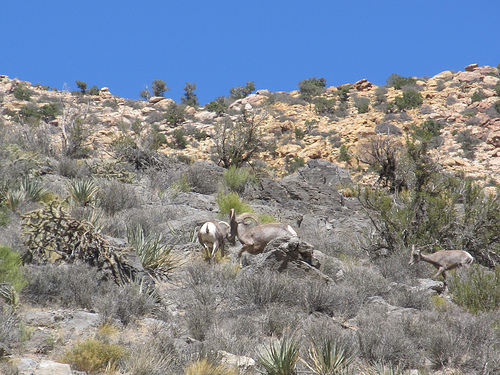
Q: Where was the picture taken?
A: A dessert.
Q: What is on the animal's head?
A: Horns.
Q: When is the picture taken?
A: Daytime.